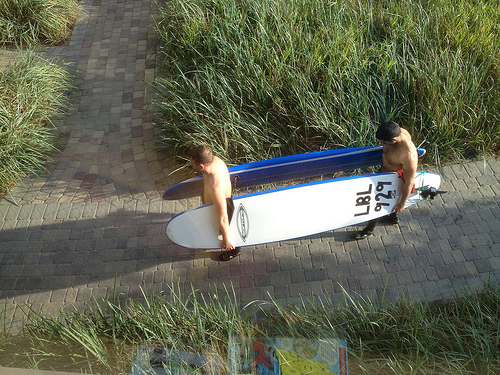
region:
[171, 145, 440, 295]
two men carrying surfboards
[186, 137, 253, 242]
the man does not have a shirt on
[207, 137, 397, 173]
the surfbord is blue in color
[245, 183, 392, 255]
the surfboard is whit in color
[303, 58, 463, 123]
the grasses ar e beside the road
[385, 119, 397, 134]
Man has short hair.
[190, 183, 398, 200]
Blue edging on board.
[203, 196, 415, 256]
2 men carrying white surfboard.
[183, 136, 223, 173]
Man has brown hair.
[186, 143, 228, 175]
Man has short hair.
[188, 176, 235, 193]
Man is bare chested.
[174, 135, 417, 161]
2 men carrying blue surfboard.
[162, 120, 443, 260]
Two men carrying two surfboards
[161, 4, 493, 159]
Tall grass lining the footpath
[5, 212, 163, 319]
Stones bricks of a footpath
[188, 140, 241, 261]
A shirtless man carrying surfboards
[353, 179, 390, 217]
Writing on the underside of a surfboard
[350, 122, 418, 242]
A man carrying two surfboards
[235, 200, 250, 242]
Logo on the underside of a surfboard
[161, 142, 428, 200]
A blue surfboard being carried by two men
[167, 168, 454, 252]
The underside of a surfboard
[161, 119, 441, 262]
Men carrying a pair of surfboards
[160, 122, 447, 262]
men carrying surf boards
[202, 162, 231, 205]
man has no shirt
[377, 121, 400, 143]
the hair is dark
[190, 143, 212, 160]
hair is light brown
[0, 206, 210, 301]
shadow on the ground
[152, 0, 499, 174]
the grass is tall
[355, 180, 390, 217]
the writing is black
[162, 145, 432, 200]
the board is blue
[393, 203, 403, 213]
hand of a man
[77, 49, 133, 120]
some tiles on sidewalk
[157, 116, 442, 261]
two men carrying two surfboards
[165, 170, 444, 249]
white surfboard with a black print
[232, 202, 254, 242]
oval black and white logo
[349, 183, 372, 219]
black print reading LBL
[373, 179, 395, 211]
black 929 number print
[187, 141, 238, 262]
shirtless man wearing black shoes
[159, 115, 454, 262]
two shirtless men carrying surfboards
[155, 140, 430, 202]
white line on blue surfboard's side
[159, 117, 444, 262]
two men walking while carrying surfboards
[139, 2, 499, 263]
two men near a patch of long grass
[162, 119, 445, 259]
two men with long surfboards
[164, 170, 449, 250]
large long white surfboard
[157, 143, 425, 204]
large long blue surfboard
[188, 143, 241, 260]
shirtless white man standing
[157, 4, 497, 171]
tall thick green grass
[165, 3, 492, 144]
patch of grass right of men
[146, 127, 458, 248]
two men holding surf boards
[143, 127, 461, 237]
two guys holding surf boards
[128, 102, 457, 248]
two dudes holding surf boards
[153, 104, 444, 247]
two fellas holding surf boards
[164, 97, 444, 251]
surfboards being held by men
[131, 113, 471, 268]
surfboards being held by dudes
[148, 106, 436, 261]
surfboards being held by guys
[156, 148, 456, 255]
blue and white surf boards